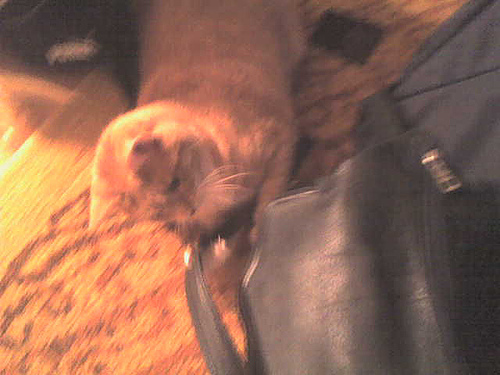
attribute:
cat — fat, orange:
[79, 58, 263, 214]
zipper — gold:
[403, 144, 446, 226]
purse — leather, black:
[279, 191, 410, 326]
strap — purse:
[178, 253, 231, 337]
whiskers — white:
[206, 174, 247, 210]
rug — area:
[27, 259, 128, 345]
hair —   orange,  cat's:
[156, 97, 187, 125]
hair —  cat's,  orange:
[192, 116, 232, 163]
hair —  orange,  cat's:
[193, 108, 233, 167]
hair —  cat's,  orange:
[189, 108, 231, 168]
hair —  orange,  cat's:
[197, 114, 231, 165]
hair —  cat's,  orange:
[200, 118, 229, 165]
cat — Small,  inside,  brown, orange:
[86, 2, 307, 249]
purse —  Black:
[186, 3, 495, 370]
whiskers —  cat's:
[196, 159, 260, 210]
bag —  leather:
[182, 0, 497, 374]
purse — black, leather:
[181, 55, 475, 370]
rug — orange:
[8, 10, 450, 371]